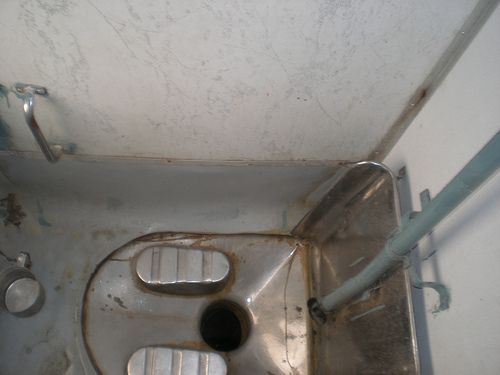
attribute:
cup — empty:
[1, 246, 51, 317]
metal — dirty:
[12, 82, 76, 162]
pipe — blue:
[322, 150, 499, 307]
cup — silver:
[5, 266, 55, 327]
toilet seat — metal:
[74, 222, 321, 374]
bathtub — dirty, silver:
[2, 151, 422, 373]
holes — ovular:
[188, 289, 266, 364]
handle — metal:
[5, 77, 87, 167]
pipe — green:
[321, 181, 451, 313]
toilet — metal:
[48, 157, 435, 373]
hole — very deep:
[188, 291, 261, 353]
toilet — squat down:
[115, 222, 281, 364]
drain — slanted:
[193, 293, 253, 356]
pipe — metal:
[308, 137, 498, 307]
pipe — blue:
[314, 92, 499, 324]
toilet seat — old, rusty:
[84, 204, 351, 372]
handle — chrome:
[15, 80, 80, 182]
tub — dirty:
[74, 155, 424, 373]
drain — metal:
[199, 297, 255, 352]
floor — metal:
[8, 165, 326, 374]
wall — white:
[69, 4, 409, 154]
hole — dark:
[196, 290, 261, 355]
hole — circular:
[197, 297, 252, 352]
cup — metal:
[6, 250, 80, 325]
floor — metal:
[12, 207, 317, 374]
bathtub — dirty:
[0, 217, 321, 370]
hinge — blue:
[392, 190, 451, 312]